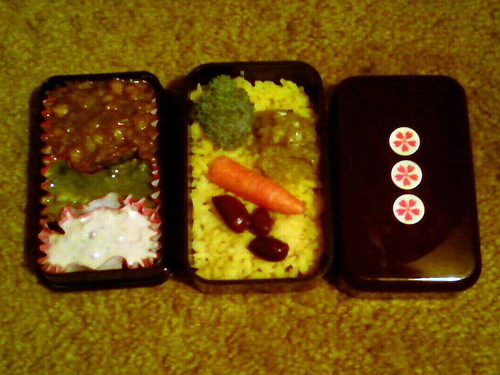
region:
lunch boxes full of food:
[30, 58, 482, 295]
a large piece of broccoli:
[192, 75, 252, 148]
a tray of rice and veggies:
[189, 73, 319, 278]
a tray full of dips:
[44, 79, 154, 270]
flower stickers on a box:
[387, 123, 426, 228]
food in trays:
[16, 49, 378, 313]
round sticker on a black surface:
[381, 113, 426, 167]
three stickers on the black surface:
[353, 115, 440, 236]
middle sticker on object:
[369, 155, 430, 198]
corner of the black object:
[427, 228, 494, 308]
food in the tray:
[190, 78, 317, 250]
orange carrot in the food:
[203, 152, 310, 220]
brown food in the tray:
[57, 80, 152, 159]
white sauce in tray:
[56, 208, 151, 264]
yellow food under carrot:
[191, 217, 249, 273]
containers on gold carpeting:
[10, 17, 489, 365]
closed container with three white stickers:
[326, 72, 481, 293]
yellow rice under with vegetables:
[181, 60, 320, 287]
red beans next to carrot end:
[205, 157, 307, 262]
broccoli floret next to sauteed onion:
[196, 81, 313, 177]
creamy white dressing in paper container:
[35, 197, 165, 273]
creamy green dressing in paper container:
[36, 165, 153, 210]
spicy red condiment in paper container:
[40, 80, 155, 165]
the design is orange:
[397, 167, 422, 187]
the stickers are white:
[385, 120, 442, 247]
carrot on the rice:
[209, 155, 314, 220]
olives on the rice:
[211, 205, 292, 273]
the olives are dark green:
[210, 201, 295, 281]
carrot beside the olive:
[196, 156, 297, 268]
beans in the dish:
[46, 93, 148, 165]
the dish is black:
[45, 270, 168, 302]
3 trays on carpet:
[15, 11, 496, 362]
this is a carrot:
[208, 143, 318, 228]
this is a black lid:
[328, 31, 482, 316]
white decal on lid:
[379, 111, 437, 233]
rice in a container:
[200, 80, 311, 270]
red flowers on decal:
[388, 115, 437, 232]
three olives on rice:
[205, 188, 296, 268]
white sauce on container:
[46, 191, 154, 268]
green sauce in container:
[49, 148, 149, 218]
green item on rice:
[192, 60, 259, 157]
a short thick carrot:
[204, 154, 304, 225]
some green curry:
[196, 78, 261, 150]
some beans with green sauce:
[42, 79, 158, 171]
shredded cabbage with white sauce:
[39, 195, 164, 268]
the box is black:
[324, 85, 481, 291]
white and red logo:
[388, 127, 423, 225]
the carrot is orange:
[208, 154, 311, 214]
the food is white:
[44, 204, 158, 276]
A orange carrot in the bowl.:
[206, 159, 301, 211]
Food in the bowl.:
[200, 83, 320, 272]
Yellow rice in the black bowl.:
[197, 211, 240, 275]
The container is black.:
[336, 76, 463, 292]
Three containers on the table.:
[17, 69, 473, 296]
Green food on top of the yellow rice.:
[197, 82, 246, 137]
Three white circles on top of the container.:
[387, 123, 424, 238]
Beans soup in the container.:
[50, 99, 147, 165]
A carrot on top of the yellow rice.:
[216, 151, 306, 233]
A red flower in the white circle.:
[396, 130, 417, 153]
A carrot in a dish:
[203, 156, 306, 216]